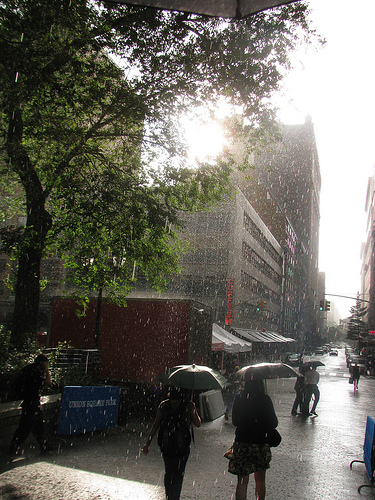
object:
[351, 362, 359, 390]
person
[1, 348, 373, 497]
sidewalk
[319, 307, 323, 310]
green light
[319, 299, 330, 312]
traffic fixture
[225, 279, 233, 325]
neon sign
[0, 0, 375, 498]
building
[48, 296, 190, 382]
sign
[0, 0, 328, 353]
tree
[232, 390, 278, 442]
coat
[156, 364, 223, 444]
umbrella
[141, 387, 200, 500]
person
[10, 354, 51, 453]
person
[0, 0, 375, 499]
rain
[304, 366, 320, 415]
man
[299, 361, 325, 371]
umbrella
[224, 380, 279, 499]
people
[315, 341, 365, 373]
parked cars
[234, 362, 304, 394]
umbrella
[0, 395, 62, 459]
wall